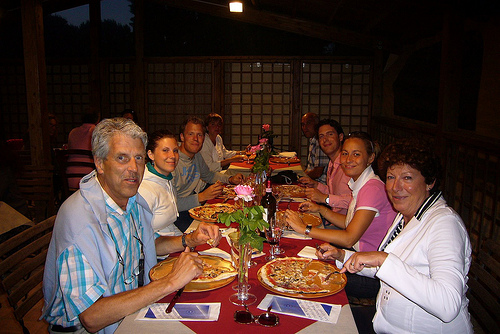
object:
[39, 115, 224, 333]
man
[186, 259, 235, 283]
pizza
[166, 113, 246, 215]
man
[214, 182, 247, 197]
pizza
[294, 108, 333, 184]
man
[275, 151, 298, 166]
pizza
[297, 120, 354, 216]
man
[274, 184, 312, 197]
pizza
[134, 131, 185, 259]
woman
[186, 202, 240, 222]
pizza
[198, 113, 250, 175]
woman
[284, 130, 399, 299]
woman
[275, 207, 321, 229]
pizza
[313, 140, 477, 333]
woman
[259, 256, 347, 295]
pizza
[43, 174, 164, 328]
shirt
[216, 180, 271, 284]
flowers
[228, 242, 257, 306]
vase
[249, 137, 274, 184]
flowers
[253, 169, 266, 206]
vase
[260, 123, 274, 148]
flowers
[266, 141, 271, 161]
vase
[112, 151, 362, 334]
table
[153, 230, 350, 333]
tablecloth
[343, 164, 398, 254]
shirt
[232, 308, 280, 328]
sunglasses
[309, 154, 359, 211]
shirt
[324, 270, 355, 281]
fork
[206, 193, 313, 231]
tablecloth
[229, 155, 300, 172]
tablecloth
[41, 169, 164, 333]
sweater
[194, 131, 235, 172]
shirt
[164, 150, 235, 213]
gray shirt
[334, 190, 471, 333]
jacket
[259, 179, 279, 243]
bottle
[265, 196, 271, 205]
brown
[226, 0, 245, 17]
light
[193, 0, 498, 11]
ceiling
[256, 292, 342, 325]
napkin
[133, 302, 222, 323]
napkin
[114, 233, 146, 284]
glasses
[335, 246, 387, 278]
hand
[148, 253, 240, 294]
plate